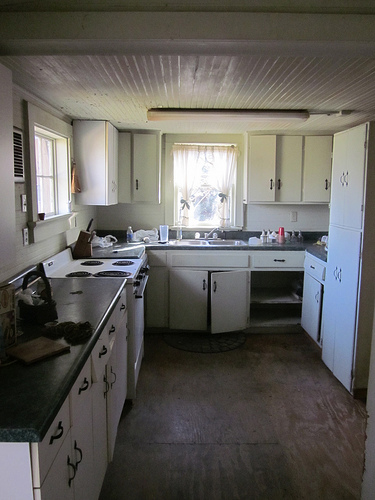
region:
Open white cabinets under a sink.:
[169, 266, 250, 333]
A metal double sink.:
[171, 237, 246, 247]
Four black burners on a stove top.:
[66, 260, 132, 277]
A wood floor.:
[106, 327, 363, 498]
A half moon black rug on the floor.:
[163, 331, 246, 354]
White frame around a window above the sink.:
[163, 133, 244, 231]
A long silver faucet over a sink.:
[205, 226, 222, 242]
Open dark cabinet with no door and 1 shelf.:
[249, 268, 303, 328]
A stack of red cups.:
[277, 225, 285, 245]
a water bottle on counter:
[124, 221, 133, 246]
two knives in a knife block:
[69, 215, 100, 260]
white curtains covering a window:
[172, 157, 240, 221]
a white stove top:
[31, 253, 145, 286]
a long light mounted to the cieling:
[135, 107, 315, 122]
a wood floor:
[216, 361, 316, 462]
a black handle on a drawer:
[265, 257, 289, 265]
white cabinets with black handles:
[241, 137, 327, 214]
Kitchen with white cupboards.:
[1, 119, 374, 498]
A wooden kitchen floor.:
[103, 322, 365, 499]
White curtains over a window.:
[171, 140, 243, 230]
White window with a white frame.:
[25, 104, 74, 244]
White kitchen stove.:
[40, 247, 148, 398]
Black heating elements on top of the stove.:
[64, 260, 136, 279]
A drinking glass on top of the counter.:
[156, 224, 171, 243]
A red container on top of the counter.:
[274, 223, 287, 246]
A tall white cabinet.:
[318, 142, 373, 399]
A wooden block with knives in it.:
[71, 217, 97, 257]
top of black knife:
[84, 215, 96, 224]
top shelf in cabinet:
[261, 280, 281, 293]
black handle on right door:
[211, 280, 219, 292]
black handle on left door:
[198, 278, 208, 294]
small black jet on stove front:
[110, 256, 135, 266]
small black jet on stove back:
[79, 255, 106, 266]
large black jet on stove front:
[94, 270, 131, 277]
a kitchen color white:
[3, 54, 373, 483]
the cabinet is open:
[160, 264, 258, 345]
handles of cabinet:
[199, 277, 222, 296]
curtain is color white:
[162, 137, 243, 239]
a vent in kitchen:
[12, 117, 30, 188]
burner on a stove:
[63, 251, 141, 282]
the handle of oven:
[130, 263, 152, 300]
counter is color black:
[10, 265, 126, 452]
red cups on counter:
[274, 224, 287, 247]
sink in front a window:
[165, 197, 248, 246]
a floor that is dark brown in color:
[158, 342, 316, 477]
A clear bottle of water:
[123, 223, 135, 243]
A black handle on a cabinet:
[63, 452, 77, 490]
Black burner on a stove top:
[95, 267, 130, 278]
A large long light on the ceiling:
[146, 102, 316, 127]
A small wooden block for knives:
[72, 213, 97, 258]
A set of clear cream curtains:
[169, 139, 238, 230]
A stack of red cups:
[275, 225, 288, 243]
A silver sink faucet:
[192, 225, 222, 239]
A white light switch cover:
[19, 192, 31, 215]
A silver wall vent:
[12, 124, 28, 185]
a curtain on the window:
[167, 133, 271, 234]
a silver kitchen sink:
[166, 216, 243, 244]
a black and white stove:
[48, 240, 118, 282]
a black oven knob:
[131, 281, 142, 292]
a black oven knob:
[136, 272, 142, 279]